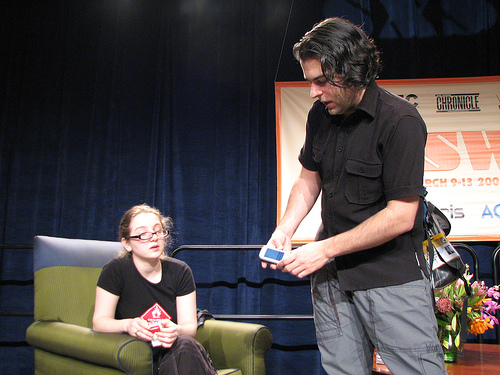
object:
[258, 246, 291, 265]
cell phone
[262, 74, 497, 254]
sign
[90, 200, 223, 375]
girl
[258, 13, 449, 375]
man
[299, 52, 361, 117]
face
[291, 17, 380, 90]
black hair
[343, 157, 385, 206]
pocket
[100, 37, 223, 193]
curtain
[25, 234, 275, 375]
chair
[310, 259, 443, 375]
pants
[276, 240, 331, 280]
hand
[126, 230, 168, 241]
glasses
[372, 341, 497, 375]
table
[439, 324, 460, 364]
vase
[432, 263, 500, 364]
flowers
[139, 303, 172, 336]
red card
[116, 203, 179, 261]
blonde hair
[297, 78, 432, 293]
shirt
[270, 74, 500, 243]
orange trim